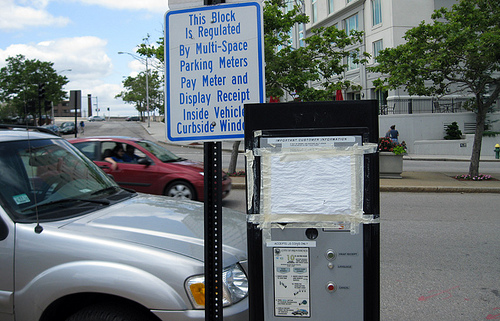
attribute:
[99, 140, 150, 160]
shirt — blue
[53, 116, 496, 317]
pavement — grey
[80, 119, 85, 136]
person — walking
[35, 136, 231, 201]
car — red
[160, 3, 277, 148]
sign — white, blue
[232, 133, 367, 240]
paper — white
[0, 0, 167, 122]
clouds — white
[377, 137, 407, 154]
plant — large, potted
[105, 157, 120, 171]
arm — person's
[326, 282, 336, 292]
button — red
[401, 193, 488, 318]
road — grey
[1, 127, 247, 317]
car — silver, grey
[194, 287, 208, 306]
headlight — orange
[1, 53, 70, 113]
leaves — green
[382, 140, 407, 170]
plant — potted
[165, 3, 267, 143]
sign — rectangle, white, blue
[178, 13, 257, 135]
writing — blue